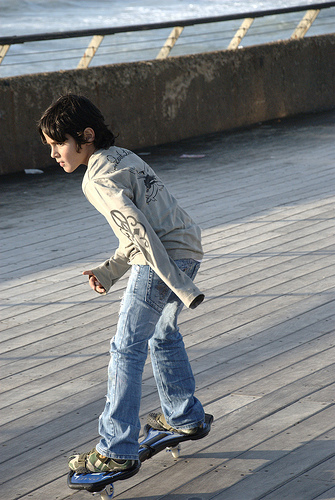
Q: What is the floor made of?
A: Wood.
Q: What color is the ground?
A: Brown.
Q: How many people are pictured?
A: 1.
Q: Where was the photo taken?
A: The beach.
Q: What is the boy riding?
A: A skateboard.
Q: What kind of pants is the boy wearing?
A: Jeans.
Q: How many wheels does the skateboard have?
A: 2.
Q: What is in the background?
A: The ocean.